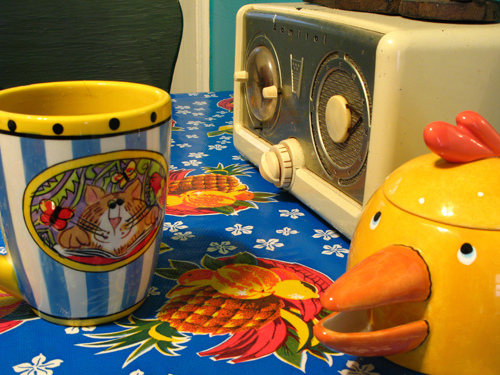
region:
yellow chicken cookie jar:
[303, 109, 498, 374]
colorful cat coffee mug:
[1, 78, 166, 330]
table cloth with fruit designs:
[3, 76, 324, 372]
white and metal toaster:
[211, 2, 498, 211]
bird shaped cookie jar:
[303, 112, 495, 369]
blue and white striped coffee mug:
[0, 77, 167, 329]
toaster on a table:
[224, 3, 499, 233]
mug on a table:
[4, 67, 184, 367]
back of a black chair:
[4, 0, 196, 105]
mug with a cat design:
[1, 60, 169, 352]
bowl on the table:
[294, 99, 498, 371]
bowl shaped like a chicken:
[312, 113, 496, 370]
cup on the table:
[6, 73, 198, 333]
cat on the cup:
[32, 162, 218, 271]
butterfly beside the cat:
[36, 196, 75, 231]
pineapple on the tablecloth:
[109, 281, 259, 371]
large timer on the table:
[231, 7, 482, 223]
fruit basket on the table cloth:
[176, 241, 333, 372]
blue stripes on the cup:
[0, 134, 177, 336]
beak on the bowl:
[301, 243, 438, 363]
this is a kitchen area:
[16, 16, 473, 366]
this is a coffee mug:
[7, 87, 137, 252]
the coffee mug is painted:
[10, 85, 163, 260]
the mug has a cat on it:
[24, 136, 194, 294]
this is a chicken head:
[357, 196, 470, 325]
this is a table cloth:
[172, 248, 347, 370]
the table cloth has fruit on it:
[173, 245, 312, 367]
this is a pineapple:
[144, 298, 219, 338]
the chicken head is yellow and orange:
[312, 205, 484, 337]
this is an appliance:
[203, 20, 432, 170]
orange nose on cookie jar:
[318, 227, 415, 355]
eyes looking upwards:
[364, 197, 481, 261]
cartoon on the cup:
[25, 172, 160, 257]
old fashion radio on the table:
[227, 36, 399, 201]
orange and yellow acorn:
[148, 306, 272, 340]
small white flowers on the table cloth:
[223, 211, 313, 252]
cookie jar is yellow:
[317, 171, 494, 373]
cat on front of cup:
[78, 179, 155, 249]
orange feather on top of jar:
[433, 107, 491, 179]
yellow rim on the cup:
[11, 83, 157, 125]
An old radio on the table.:
[204, 24, 431, 189]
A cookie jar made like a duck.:
[363, 148, 498, 325]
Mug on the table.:
[31, 77, 183, 324]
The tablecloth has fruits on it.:
[176, 217, 311, 349]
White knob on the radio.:
[253, 127, 296, 186]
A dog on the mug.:
[63, 179, 167, 259]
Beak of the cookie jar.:
[315, 260, 427, 352]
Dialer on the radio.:
[303, 71, 371, 161]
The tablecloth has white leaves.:
[164, 97, 279, 288]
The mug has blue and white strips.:
[14, 144, 125, 323]